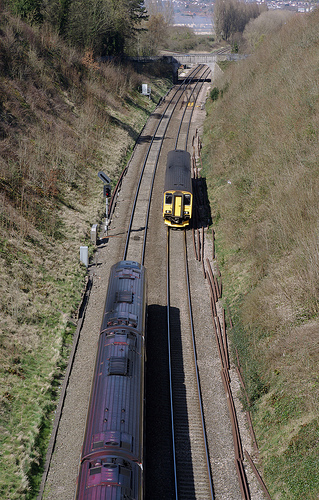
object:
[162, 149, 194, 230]
car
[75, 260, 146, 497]
car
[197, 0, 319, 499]
grass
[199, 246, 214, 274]
gravel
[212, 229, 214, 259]
board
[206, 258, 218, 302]
log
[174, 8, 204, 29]
body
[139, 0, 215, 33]
water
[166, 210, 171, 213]
light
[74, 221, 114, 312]
area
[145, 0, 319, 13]
building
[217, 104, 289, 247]
vegetation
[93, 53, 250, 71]
bridge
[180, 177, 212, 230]
shadow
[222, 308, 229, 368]
rod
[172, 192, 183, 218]
door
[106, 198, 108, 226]
pole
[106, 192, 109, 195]
signal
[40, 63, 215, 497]
rail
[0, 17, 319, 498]
ground